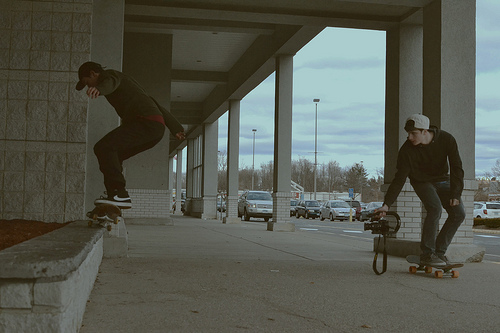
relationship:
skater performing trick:
[74, 56, 191, 241] [82, 183, 134, 231]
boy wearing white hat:
[373, 113, 466, 265] [408, 113, 431, 131]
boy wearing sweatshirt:
[326, 77, 484, 315] [380, 131, 474, 207]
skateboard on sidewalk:
[407, 250, 463, 278] [76, 212, 498, 332]